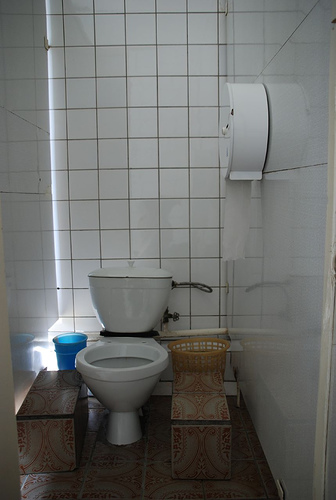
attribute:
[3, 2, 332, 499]
bathroom — white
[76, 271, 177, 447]
toilet — white, ceramic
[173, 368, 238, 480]
shelf — brown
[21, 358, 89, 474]
shelf — brown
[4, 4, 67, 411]
wall — white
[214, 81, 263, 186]
toilet paper holder — white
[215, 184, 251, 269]
toilet paper — white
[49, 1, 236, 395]
tile — white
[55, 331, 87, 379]
bucket — blue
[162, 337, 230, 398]
basket — tan, yellow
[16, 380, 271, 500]
floor — tiled, brown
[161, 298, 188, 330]
pipe — white